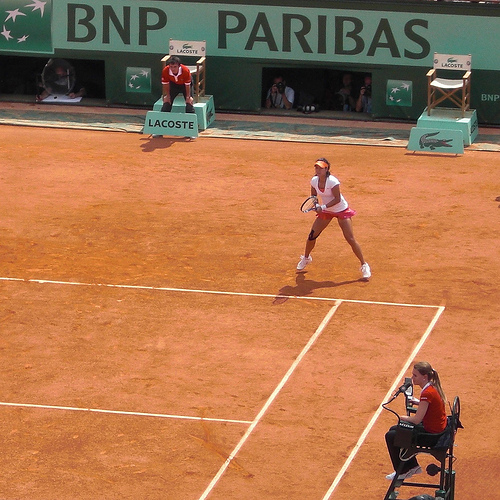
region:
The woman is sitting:
[376, 347, 456, 479]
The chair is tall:
[376, 390, 463, 495]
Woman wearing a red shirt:
[403, 354, 462, 439]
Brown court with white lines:
[14, 189, 479, 491]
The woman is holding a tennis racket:
[289, 154, 381, 281]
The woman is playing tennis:
[283, 152, 378, 294]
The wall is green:
[37, 5, 472, 80]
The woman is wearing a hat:
[301, 151, 338, 184]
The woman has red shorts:
[288, 153, 380, 286]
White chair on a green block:
[401, 52, 476, 157]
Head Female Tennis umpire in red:
[382, 361, 452, 483]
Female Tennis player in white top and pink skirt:
[285, 157, 374, 284]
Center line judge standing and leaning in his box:
[142, 28, 217, 140]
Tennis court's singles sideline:
[198, 288, 345, 497]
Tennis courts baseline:
[0, 273, 453, 312]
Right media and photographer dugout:
[259, 62, 375, 119]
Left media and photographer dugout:
[0, 53, 108, 105]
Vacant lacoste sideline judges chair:
[418, 44, 476, 114]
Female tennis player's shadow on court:
[267, 272, 385, 306]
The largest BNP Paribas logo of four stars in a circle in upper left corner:
[4, 1, 54, 53]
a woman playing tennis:
[252, 129, 389, 321]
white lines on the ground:
[22, 238, 317, 442]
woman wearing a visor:
[303, 155, 332, 179]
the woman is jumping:
[247, 239, 377, 289]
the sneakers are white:
[257, 243, 379, 278]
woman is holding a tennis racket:
[288, 181, 335, 228]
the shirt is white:
[281, 167, 359, 217]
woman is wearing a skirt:
[273, 192, 368, 227]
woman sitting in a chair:
[355, 342, 465, 484]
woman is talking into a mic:
[348, 336, 478, 475]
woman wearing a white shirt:
[294, 149, 375, 281]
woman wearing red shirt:
[394, 354, 456, 445]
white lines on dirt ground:
[5, 258, 460, 363]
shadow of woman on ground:
[267, 268, 371, 315]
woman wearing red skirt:
[293, 151, 356, 226]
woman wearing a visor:
[297, 153, 363, 233]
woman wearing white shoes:
[290, 155, 380, 283]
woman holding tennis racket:
[294, 149, 353, 234]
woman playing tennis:
[296, 155, 375, 286]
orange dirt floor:
[23, 165, 252, 274]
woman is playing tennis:
[290, 154, 372, 281]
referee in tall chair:
[371, 358, 463, 498]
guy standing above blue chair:
[142, 53, 205, 143]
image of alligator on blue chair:
[407, 125, 461, 156]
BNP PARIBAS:
[66, 0, 433, 77]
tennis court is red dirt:
[0, 268, 447, 499]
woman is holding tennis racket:
[299, 193, 324, 215]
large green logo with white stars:
[0, 0, 56, 53]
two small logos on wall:
[120, 65, 417, 117]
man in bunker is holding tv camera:
[35, 55, 84, 103]